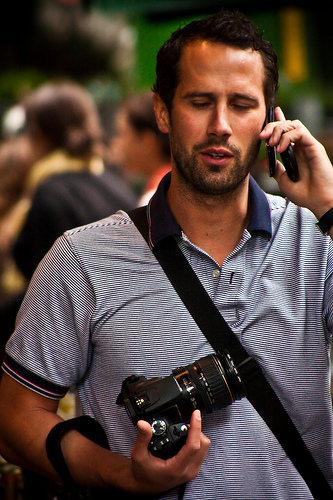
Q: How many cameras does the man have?
A: One.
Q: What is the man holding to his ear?
A: A cellphone.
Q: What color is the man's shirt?
A: Blue.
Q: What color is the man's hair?
A: Brown.